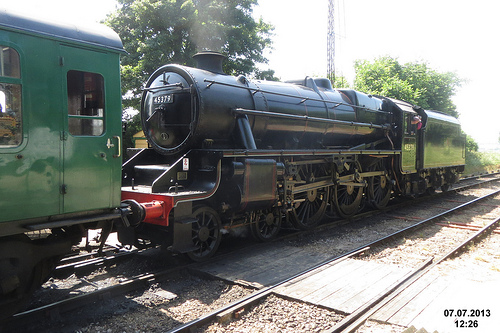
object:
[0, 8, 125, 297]
railroad car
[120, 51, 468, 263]
locomotive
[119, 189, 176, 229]
coupling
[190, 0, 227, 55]
smoke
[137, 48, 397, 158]
engine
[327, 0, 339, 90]
radio tower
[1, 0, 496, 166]
background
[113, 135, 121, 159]
door handle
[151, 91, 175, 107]
number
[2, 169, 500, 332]
train track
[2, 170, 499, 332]
gravel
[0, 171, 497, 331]
tracks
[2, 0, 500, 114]
sky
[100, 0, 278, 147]
tree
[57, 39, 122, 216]
door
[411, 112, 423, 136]
conductor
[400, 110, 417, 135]
window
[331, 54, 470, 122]
tree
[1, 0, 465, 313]
train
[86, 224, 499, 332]
walkway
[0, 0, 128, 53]
roof